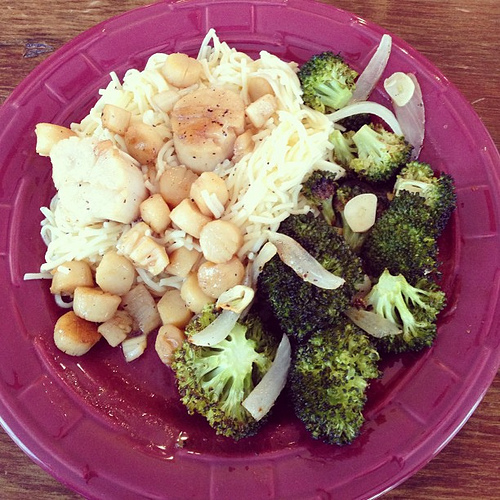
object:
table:
[1, 1, 500, 497]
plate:
[1, 1, 500, 500]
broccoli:
[171, 307, 278, 442]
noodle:
[43, 235, 108, 272]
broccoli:
[348, 123, 415, 183]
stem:
[350, 124, 377, 151]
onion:
[264, 230, 346, 290]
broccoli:
[254, 213, 364, 343]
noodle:
[240, 57, 248, 106]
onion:
[241, 332, 294, 424]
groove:
[10, 369, 46, 399]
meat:
[170, 88, 246, 174]